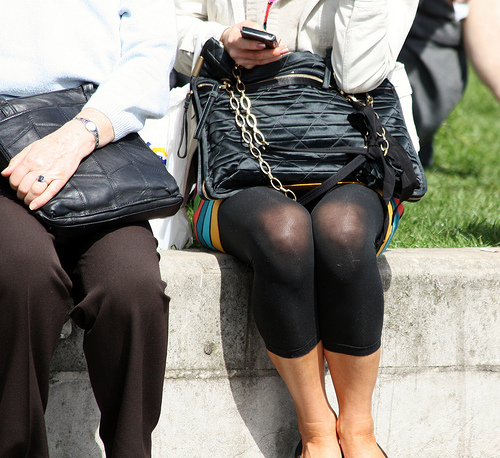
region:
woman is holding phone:
[200, 11, 318, 81]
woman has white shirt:
[220, 8, 458, 96]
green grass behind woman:
[405, 124, 482, 242]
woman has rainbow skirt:
[171, 173, 222, 274]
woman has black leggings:
[222, 163, 379, 364]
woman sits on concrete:
[388, 230, 493, 454]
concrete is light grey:
[342, 188, 487, 450]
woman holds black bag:
[207, 40, 422, 202]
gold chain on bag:
[211, 94, 319, 212]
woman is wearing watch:
[67, 97, 98, 169]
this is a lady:
[226, 8, 423, 350]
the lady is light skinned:
[301, 392, 336, 434]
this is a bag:
[239, 82, 348, 158]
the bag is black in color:
[282, 101, 337, 163]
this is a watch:
[77, 114, 104, 133]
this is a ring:
[35, 173, 54, 188]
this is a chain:
[230, 78, 266, 150]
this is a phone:
[238, 22, 284, 57]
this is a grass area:
[441, 178, 494, 236]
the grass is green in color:
[432, 175, 497, 245]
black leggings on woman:
[230, 184, 397, 350]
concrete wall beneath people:
[49, 267, 480, 406]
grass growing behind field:
[408, 207, 499, 264]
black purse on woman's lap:
[201, 50, 388, 177]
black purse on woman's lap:
[5, 80, 180, 210]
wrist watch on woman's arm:
[65, 110, 112, 160]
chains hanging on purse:
[236, 92, 274, 143]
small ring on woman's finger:
[38, 167, 46, 196]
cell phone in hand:
[239, 16, 283, 55]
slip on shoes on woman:
[278, 410, 369, 456]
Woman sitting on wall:
[172, 2, 425, 456]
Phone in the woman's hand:
[230, 19, 282, 54]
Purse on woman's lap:
[185, 42, 425, 207]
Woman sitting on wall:
[2, 0, 181, 457]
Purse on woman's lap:
[2, 79, 192, 224]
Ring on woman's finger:
[30, 166, 47, 187]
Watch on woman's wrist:
[65, 108, 106, 150]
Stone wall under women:
[0, 246, 498, 455]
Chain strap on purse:
[220, 83, 304, 203]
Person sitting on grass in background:
[387, 0, 499, 166]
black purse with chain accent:
[176, 37, 431, 203]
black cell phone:
[238, 21, 281, 49]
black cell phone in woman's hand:
[218, 18, 293, 67]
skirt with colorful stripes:
[182, 173, 406, 256]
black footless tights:
[216, 185, 396, 358]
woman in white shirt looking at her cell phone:
[172, 0, 432, 457]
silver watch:
[68, 110, 104, 148]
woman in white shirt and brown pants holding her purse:
[1, 5, 178, 456]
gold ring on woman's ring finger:
[33, 172, 53, 187]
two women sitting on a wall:
[1, 0, 498, 454]